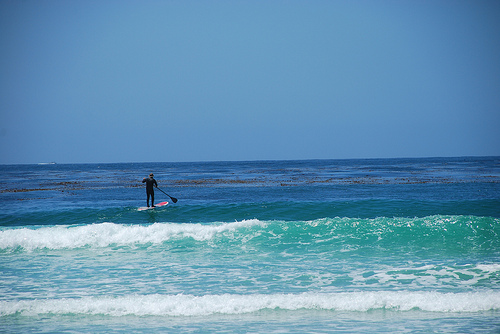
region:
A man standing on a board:
[139, 170, 159, 205]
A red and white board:
[140, 199, 167, 212]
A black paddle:
[151, 182, 178, 203]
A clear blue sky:
[1, 0, 498, 162]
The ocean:
[2, 163, 497, 332]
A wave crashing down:
[1, 223, 244, 255]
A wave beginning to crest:
[253, 213, 498, 254]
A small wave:
[0, 291, 499, 316]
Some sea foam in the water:
[0, 250, 499, 294]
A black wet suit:
[142, 176, 157, 206]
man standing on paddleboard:
[131, 170, 166, 222]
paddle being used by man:
[151, 186, 183, 208]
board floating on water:
[136, 194, 171, 212]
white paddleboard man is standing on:
[130, 198, 172, 216]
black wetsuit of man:
[142, 179, 160, 208]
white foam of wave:
[11, 220, 280, 260]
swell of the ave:
[264, 224, 499, 254]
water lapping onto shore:
[10, 290, 499, 327]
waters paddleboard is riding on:
[10, 165, 499, 225]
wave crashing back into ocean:
[7, 220, 483, 268]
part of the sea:
[386, 254, 398, 264]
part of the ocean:
[219, 228, 228, 238]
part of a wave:
[103, 228, 120, 248]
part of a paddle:
[167, 194, 180, 199]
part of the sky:
[269, 127, 282, 147]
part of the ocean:
[86, 161, 96, 172]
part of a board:
[159, 198, 163, 208]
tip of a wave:
[349, 238, 354, 248]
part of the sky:
[357, 128, 370, 143]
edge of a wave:
[378, 209, 387, 221]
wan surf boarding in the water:
[134, 169, 180, 214]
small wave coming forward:
[166, 272, 356, 320]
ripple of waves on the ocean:
[229, 178, 346, 248]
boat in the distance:
[30, 155, 66, 172]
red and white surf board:
[135, 197, 167, 219]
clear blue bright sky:
[167, 18, 384, 104]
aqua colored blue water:
[296, 225, 381, 258]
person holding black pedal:
[151, 181, 188, 208]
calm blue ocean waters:
[202, 163, 332, 209]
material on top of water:
[15, 173, 102, 201]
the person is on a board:
[134, 174, 174, 210]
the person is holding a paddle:
[139, 173, 174, 212]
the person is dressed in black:
[136, 170, 173, 210]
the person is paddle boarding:
[136, 167, 175, 213]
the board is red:
[137, 170, 179, 212]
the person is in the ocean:
[136, 171, 173, 211]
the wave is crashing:
[0, 216, 499, 330]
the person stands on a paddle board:
[136, 171, 173, 209]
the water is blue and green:
[1, 155, 499, 332]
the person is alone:
[136, 175, 178, 210]